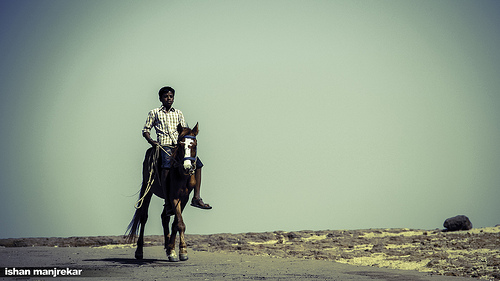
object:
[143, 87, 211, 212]
young boy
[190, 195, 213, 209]
sandals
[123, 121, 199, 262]
buildings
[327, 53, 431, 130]
sky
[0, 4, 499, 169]
sky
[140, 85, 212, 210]
boy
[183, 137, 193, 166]
white blaze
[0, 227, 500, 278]
terrain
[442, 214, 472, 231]
rock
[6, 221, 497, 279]
road`s side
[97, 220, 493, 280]
brush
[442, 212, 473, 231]
stone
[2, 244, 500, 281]
road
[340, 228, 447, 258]
sand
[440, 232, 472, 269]
sand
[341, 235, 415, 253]
road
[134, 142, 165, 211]
rope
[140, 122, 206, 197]
pole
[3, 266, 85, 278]
name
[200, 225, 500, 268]
rocky terrain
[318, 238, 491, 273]
sand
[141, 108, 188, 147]
shirt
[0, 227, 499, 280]
beach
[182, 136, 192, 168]
blaze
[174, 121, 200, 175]
face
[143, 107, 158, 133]
sleeve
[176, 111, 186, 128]
sleeve